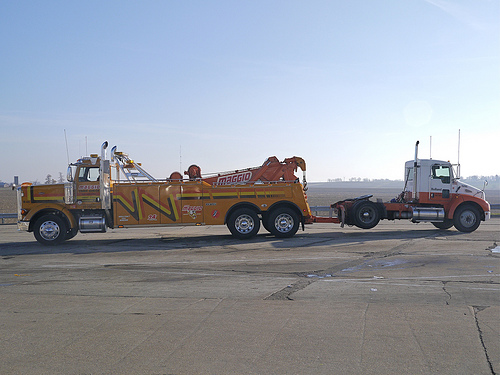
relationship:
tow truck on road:
[34, 145, 316, 238] [235, 243, 409, 339]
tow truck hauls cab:
[34, 145, 316, 238] [323, 150, 493, 247]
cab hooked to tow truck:
[328, 128, 491, 234] [34, 145, 316, 238]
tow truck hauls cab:
[34, 145, 316, 238] [328, 128, 491, 234]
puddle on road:
[314, 245, 411, 293] [235, 243, 409, 339]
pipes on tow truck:
[90, 146, 121, 190] [34, 145, 316, 238]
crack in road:
[267, 257, 337, 306] [235, 243, 409, 339]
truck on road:
[323, 150, 493, 247] [235, 243, 409, 339]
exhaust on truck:
[406, 139, 424, 165] [323, 150, 493, 247]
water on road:
[338, 247, 410, 264] [235, 243, 409, 339]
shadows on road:
[23, 225, 443, 250] [235, 243, 409, 339]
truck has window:
[323, 150, 493, 247] [428, 163, 450, 181]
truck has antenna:
[323, 150, 493, 247] [425, 124, 470, 182]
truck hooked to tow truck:
[323, 150, 493, 247] [34, 145, 316, 238]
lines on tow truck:
[101, 190, 206, 221] [34, 145, 316, 238]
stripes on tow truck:
[72, 175, 279, 224] [34, 145, 316, 238]